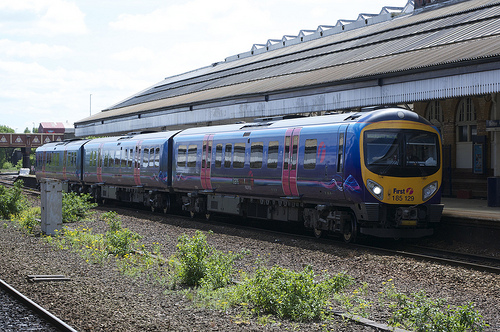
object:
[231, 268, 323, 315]
bushes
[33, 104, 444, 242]
passenger train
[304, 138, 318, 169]
windows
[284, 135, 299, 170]
window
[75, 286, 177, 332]
gravel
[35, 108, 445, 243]
blue train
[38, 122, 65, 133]
rooftop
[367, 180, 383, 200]
headlight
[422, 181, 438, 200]
headlight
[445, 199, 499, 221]
platform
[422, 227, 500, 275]
train tracks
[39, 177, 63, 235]
box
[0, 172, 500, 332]
track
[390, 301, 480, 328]
weeds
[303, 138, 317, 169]
window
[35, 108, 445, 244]
train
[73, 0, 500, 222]
station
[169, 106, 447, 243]
car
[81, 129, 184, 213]
car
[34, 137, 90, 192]
car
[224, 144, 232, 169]
window